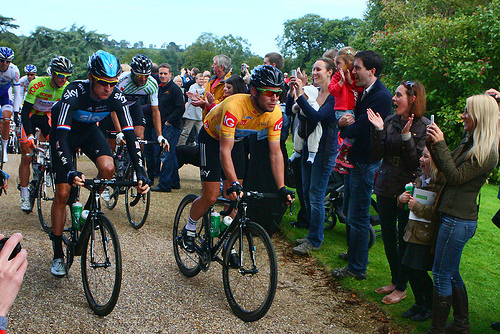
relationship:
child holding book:
[397, 146, 442, 320] [408, 188, 437, 223]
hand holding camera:
[1, 229, 28, 311] [3, 232, 23, 258]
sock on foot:
[48, 235, 68, 258] [48, 255, 71, 282]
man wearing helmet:
[35, 46, 140, 282] [79, 48, 124, 78]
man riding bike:
[35, 46, 140, 282] [131, 155, 286, 332]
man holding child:
[336, 52, 387, 282] [325, 47, 360, 170]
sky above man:
[1, 0, 372, 58] [182, 65, 295, 269]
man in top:
[11, 55, 72, 207] [20, 70, 72, 117]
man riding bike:
[11, 55, 72, 207] [221, 205, 298, 316]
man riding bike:
[182, 65, 295, 269] [172, 186, 293, 322]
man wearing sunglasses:
[172, 65, 299, 255] [249, 83, 288, 98]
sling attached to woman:
[296, 113, 322, 138] [284, 55, 340, 254]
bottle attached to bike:
[216, 204, 226, 239] [147, 177, 279, 316]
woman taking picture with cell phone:
[416, 71, 493, 243] [416, 109, 438, 140]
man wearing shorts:
[182, 65, 295, 269] [196, 132, 256, 185]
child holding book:
[393, 140, 443, 330] [404, 183, 437, 223]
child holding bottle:
[393, 140, 443, 330] [395, 175, 417, 205]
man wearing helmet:
[182, 65, 295, 269] [249, 63, 284, 89]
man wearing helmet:
[52, 49, 152, 276] [82, 46, 128, 86]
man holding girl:
[330, 51, 391, 281] [318, 40, 363, 130]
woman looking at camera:
[306, 61, 336, 117] [291, 69, 297, 76]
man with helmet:
[330, 51, 391, 281] [247, 64, 292, 94]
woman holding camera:
[285, 58, 338, 255] [287, 62, 307, 89]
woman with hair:
[363, 80, 425, 306] [403, 80, 427, 117]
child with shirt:
[327, 47, 364, 174] [322, 73, 354, 109]